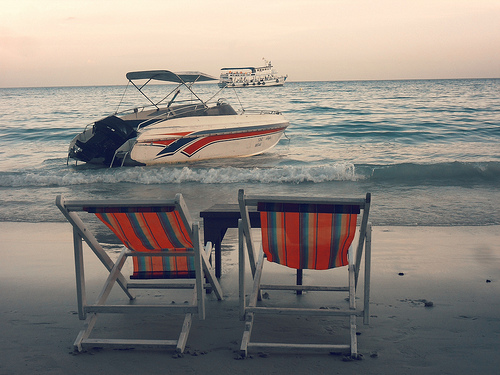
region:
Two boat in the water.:
[113, 50, 310, 179]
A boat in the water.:
[186, 46, 331, 94]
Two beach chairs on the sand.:
[49, 173, 390, 341]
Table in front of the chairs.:
[193, 187, 327, 266]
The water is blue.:
[301, 78, 450, 173]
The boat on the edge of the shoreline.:
[81, 61, 290, 177]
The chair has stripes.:
[253, 185, 355, 276]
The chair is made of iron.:
[61, 253, 226, 363]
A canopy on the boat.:
[123, 55, 235, 98]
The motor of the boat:
[62, 103, 133, 163]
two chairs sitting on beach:
[51, 176, 393, 356]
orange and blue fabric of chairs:
[87, 198, 352, 288]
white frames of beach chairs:
[54, 190, 375, 361]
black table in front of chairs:
[196, 197, 364, 288]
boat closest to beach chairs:
[67, 58, 290, 160]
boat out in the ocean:
[211, 59, 289, 95]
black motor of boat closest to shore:
[74, 113, 124, 163]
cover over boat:
[120, 61, 219, 113]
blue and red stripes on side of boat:
[140, 130, 279, 156]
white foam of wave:
[9, 166, 367, 196]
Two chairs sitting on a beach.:
[55, 191, 366, 354]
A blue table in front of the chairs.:
[197, 199, 309, 288]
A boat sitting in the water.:
[65, 70, 286, 166]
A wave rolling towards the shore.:
[0, 165, 495, 185]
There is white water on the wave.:
[30, 162, 345, 178]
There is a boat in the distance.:
[211, 60, 279, 87]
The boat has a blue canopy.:
[125, 66, 215, 101]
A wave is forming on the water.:
[0, 116, 75, 151]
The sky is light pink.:
[0, 0, 495, 85]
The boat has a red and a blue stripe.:
[145, 126, 271, 152]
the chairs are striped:
[69, 163, 384, 328]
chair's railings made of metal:
[40, 171, 225, 357]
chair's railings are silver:
[20, 174, 227, 362]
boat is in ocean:
[36, 28, 315, 220]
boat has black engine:
[75, 118, 127, 163]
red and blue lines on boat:
[135, 116, 237, 164]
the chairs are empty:
[45, 170, 341, 336]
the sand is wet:
[379, 217, 498, 340]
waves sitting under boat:
[81, 154, 378, 214]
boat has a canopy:
[122, 54, 246, 104]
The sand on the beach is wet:
[31, 266, 497, 368]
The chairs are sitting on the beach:
[47, 182, 377, 361]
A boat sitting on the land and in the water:
[57, 67, 294, 171]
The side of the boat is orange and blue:
[137, 120, 292, 161]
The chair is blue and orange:
[250, 195, 367, 273]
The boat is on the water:
[214, 55, 291, 90]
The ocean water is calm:
[324, 72, 484, 163]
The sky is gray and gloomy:
[25, 2, 492, 58]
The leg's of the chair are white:
[231, 273, 373, 360]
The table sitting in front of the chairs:
[194, 198, 309, 295]